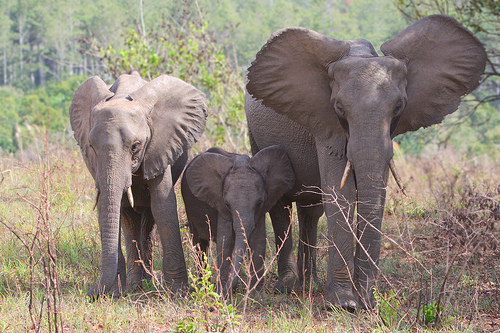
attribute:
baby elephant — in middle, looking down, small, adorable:
[177, 138, 305, 305]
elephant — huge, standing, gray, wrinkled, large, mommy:
[241, 42, 425, 309]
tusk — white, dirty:
[387, 153, 418, 203]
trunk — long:
[95, 177, 126, 306]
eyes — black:
[320, 89, 422, 127]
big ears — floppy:
[391, 39, 488, 142]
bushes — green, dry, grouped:
[164, 26, 250, 95]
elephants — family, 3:
[62, 17, 486, 309]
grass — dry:
[60, 228, 88, 246]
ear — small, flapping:
[254, 152, 298, 220]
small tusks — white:
[221, 229, 272, 231]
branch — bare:
[485, 54, 497, 83]